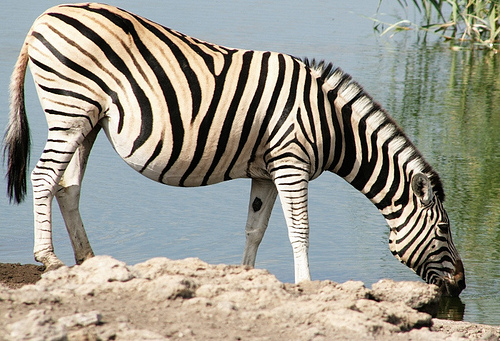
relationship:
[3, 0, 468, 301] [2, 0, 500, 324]
zebra drinking water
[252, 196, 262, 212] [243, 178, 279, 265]
spot on leg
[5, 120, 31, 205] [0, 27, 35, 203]
hair on end of tail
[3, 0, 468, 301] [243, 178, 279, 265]
zebra has leg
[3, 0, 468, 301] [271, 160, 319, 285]
zebra has leg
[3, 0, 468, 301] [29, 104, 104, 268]
zebra has leg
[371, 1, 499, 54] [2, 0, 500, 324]
plants are in water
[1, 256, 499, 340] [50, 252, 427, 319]
ground has edge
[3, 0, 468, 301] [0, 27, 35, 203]
zebra has tail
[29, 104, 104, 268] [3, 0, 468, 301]
leg in back of zebra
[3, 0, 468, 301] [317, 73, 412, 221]
zebra has neck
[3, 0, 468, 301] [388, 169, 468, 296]
zebra has head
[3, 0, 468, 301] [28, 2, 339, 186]
zebra has body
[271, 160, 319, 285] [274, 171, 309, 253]
leg has stripes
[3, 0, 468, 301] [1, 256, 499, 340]
zebra standing on ground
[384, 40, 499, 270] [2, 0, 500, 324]
reflection on water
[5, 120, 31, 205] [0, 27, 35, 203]
hair on tip of tail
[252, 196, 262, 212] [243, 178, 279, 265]
spot on inside of leg